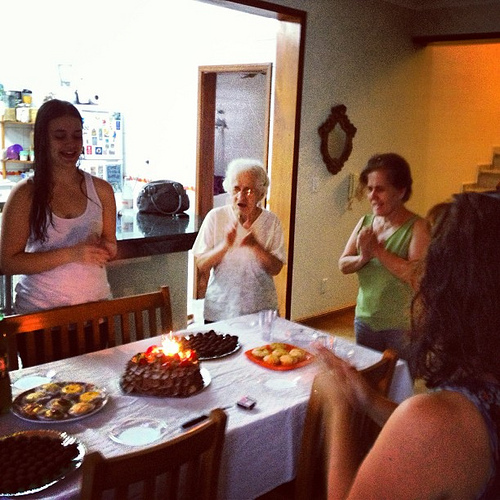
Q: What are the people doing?
A: Clapping.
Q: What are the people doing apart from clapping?
A: Singing.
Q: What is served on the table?
A: Dinner.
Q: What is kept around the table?
A: Chairs.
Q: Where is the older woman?
A: Near the corner of the table.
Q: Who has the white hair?
A: The old woman.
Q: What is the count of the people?
A: Four.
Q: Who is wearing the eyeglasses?
A: The old woman.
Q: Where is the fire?
A: On top of the cake.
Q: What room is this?
A: Dining room.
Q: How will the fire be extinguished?
A: By blowing on it.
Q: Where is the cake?
A: On the table.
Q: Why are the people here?
A: To celebrate a birthday.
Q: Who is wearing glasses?
A: Grandmother.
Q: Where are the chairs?
A: Around the table.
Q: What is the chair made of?
A: Wood.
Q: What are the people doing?
A: Celebrating a birthday.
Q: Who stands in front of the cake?
A: A girl with long brown hair.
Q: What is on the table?
A: Food.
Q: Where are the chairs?
A: Next to the table.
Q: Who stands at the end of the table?
A: A lady in a green shirt.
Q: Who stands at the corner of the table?
A: An old lady.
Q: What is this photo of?
A: A birthday.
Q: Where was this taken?
A: A party.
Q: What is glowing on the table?
A: A candle.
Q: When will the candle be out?
A: When the lady blows it out.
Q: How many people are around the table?
A: 4.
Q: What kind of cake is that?
A: Chocolate.